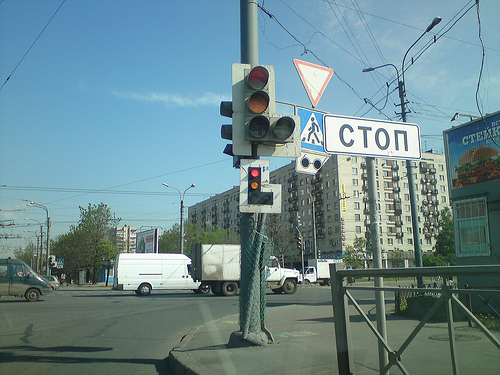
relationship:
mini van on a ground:
[113, 252, 210, 295] [0, 280, 499, 374]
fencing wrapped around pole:
[232, 218, 282, 347] [251, 217, 264, 278]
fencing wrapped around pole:
[232, 218, 282, 347] [232, 212, 269, 348]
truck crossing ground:
[191, 243, 300, 296] [0, 280, 499, 374]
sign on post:
[292, 104, 334, 155] [272, 96, 427, 171]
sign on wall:
[441, 110, 498, 197] [442, 110, 499, 317]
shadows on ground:
[7, 317, 120, 364] [403, 192, 445, 232]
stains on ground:
[93, 317, 122, 337] [403, 192, 445, 232]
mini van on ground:
[114, 249, 208, 299] [0, 280, 499, 374]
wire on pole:
[236, 221, 276, 336] [240, 214, 263, 329]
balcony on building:
[371, 201, 400, 212] [189, 149, 449, 264]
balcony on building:
[375, 212, 399, 222] [189, 149, 449, 264]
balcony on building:
[367, 219, 399, 235] [189, 149, 449, 264]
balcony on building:
[373, 190, 400, 202] [189, 149, 449, 264]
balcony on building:
[367, 179, 401, 191] [189, 149, 449, 264]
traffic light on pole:
[243, 67, 271, 145] [240, 0, 259, 69]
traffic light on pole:
[274, 112, 297, 140] [240, 0, 259, 69]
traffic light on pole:
[246, 163, 263, 205] [240, 0, 259, 69]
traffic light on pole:
[218, 95, 240, 163] [240, 0, 259, 69]